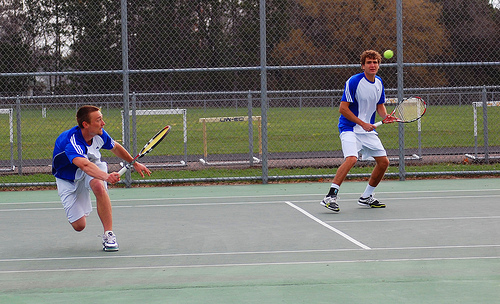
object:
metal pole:
[251, 25, 273, 173]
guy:
[321, 45, 435, 220]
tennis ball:
[381, 45, 397, 61]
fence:
[2, 0, 499, 96]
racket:
[365, 92, 431, 134]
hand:
[355, 115, 377, 137]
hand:
[381, 112, 401, 126]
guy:
[47, 104, 157, 256]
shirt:
[341, 71, 400, 137]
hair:
[359, 50, 379, 62]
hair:
[75, 105, 102, 128]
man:
[51, 104, 153, 253]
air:
[2, 2, 497, 300]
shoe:
[355, 195, 385, 206]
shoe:
[319, 191, 341, 211]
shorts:
[59, 163, 101, 221]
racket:
[112, 103, 204, 175]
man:
[311, 51, 407, 211]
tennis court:
[1, 169, 498, 301]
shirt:
[45, 119, 119, 198]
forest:
[0, 2, 484, 102]